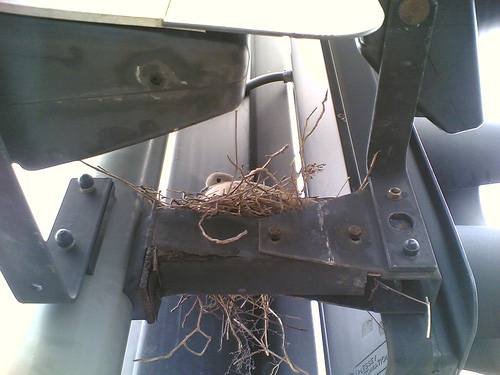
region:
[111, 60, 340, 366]
bird in twig nest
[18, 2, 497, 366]
silver iron structure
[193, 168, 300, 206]
white bird with black eye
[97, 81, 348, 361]
brown crisp twig nest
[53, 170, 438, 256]
black bolts in steel bridge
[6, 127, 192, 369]
white clear sky in back ground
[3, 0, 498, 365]
daytime sunny outdoor scene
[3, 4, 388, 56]
white curved projection over steel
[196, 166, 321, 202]
small bird with grey beak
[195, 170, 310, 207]
small round white plump bird sitting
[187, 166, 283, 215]
a bird sitting in a nest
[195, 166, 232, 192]
a little white bird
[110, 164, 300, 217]
a bird nest stting on something metal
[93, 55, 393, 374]
metal poles going down the middle of the picture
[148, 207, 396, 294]
the part the nest is sitting on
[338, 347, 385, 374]
the writing on the metal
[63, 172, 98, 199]
a bolt in the metal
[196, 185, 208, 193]
the tiny little bird beak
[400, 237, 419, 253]
another bolt in the metal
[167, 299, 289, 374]
more of the bird nest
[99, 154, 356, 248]
the sticks are brown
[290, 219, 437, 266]
the metal is black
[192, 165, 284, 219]
the bird is resting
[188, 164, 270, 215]
the bird is white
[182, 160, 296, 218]
the bird has black eyes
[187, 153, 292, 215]
the bird is small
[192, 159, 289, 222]
the bird has feathers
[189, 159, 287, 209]
the bird is lying down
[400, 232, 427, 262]
the screws are black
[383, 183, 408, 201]
the bold is rusty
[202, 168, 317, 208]
White bird in nest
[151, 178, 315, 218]
birds nest made of twigs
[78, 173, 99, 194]
metal bolts near a birds nest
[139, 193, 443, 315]
Metal bracket with birds nest on it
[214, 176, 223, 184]
Little black eyeball of a bird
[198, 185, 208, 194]
Little gray bird beak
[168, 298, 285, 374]
Small twigs hanging out of birds nest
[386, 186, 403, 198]
Gold colored nut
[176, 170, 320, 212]
Bird laying in nest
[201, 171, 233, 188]
Little bird head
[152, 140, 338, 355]
birds nest in metal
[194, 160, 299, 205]
little yellow bird sitting in nest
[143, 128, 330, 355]
brown birds nest made of twigs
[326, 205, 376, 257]
rusty metal screws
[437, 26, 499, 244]
sunlight shining around metal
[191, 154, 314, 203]
yellow bird with black eyes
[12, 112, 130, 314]
silver metal bars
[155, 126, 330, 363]
brown twigs with no leaves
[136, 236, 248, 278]
rusty crack in metal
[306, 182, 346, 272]
white bird poop on metal